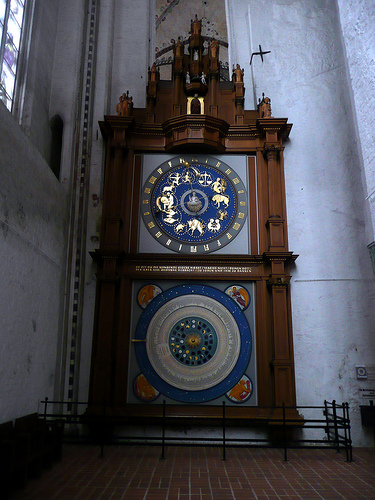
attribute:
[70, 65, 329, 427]
board — tall, uppermost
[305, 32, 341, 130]
wall — white, stone, high, gray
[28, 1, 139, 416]
pillar — straight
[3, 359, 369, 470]
fence — black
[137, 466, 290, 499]
floor — tile, red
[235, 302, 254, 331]
rim — blue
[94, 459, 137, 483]
square — brown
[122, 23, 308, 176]
statue — top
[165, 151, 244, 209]
decoration — gold, large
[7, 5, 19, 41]
window — glass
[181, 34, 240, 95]
figure — wooden